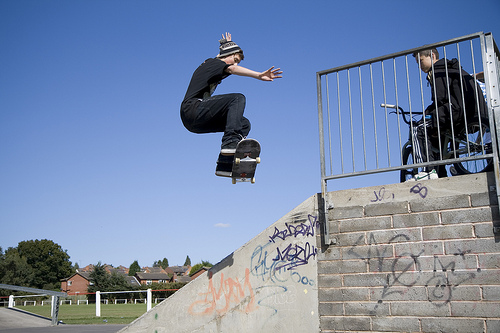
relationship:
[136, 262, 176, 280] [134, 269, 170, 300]
roof of home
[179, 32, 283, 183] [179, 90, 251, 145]
boy wearing pants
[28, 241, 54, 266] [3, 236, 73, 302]
leaves on tree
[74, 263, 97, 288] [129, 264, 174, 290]
roof top of house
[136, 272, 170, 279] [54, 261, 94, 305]
roof of house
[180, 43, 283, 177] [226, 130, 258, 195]
boy croutched over skateboard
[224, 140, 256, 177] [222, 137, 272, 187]
underside of skateboard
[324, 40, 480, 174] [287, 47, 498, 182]
poles of railing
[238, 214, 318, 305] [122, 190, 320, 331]
writing on cement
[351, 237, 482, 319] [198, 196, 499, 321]
writing on wall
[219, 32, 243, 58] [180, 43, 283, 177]
beanie on boy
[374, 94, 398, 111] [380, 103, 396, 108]
handle of handle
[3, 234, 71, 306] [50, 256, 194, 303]
tree by house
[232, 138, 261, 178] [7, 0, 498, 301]
skateboard in air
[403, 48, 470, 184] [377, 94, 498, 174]
boy on bicycle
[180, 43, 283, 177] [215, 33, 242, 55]
boy wearing hat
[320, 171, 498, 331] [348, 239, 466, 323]
wall with graffiti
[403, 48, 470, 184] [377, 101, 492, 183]
boy sitting on bicycle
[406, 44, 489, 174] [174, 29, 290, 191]
boy watching skateboarder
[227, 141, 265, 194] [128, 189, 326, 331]
skateboard on ramp